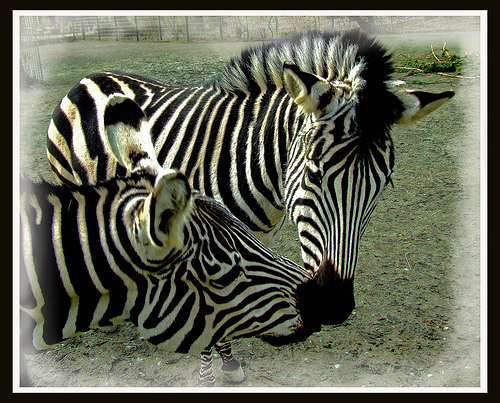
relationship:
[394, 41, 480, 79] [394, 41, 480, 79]
branches in a branches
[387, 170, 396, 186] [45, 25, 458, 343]
eyelashes on zebra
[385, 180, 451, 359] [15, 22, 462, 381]
ground surrounding zebras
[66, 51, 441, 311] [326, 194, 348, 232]
zebra has stripes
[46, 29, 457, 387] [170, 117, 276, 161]
zebra has stripes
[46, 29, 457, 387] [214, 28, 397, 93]
zebra has hair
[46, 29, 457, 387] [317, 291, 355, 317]
zebra rubbing nose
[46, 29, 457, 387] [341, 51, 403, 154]
zebra has hair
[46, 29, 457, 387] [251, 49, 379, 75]
zebra has hair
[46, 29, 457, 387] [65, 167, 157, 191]
zebra has hair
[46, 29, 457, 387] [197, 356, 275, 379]
zebra has feet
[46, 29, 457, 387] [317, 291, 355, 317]
zebra has nose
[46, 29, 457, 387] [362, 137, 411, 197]
zebra has eyelashes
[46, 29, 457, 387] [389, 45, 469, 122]
zebra in grass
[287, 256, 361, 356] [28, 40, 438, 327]
nose on zebra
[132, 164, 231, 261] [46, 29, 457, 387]
ear on zebra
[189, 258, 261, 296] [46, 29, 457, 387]
eye on zebra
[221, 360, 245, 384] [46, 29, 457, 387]
feet of zebra